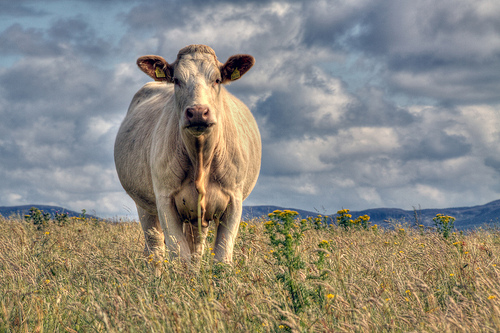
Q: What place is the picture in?
A: It is at the field.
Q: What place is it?
A: It is a field.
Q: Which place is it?
A: It is a field.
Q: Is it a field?
A: Yes, it is a field.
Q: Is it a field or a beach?
A: It is a field.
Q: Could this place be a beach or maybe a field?
A: It is a field.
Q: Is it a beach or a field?
A: It is a field.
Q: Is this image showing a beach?
A: No, the picture is showing a field.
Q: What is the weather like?
A: It is cloudy.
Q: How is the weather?
A: It is cloudy.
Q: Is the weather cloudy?
A: Yes, it is cloudy.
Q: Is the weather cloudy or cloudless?
A: It is cloudy.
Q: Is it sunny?
A: No, it is cloudy.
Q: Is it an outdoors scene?
A: Yes, it is outdoors.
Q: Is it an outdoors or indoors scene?
A: It is outdoors.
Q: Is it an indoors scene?
A: No, it is outdoors.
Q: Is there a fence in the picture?
A: No, there are no fences.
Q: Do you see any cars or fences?
A: No, there are no fences or cars.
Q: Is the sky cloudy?
A: Yes, the sky is cloudy.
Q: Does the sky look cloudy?
A: Yes, the sky is cloudy.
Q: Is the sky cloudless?
A: No, the sky is cloudy.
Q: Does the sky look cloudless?
A: No, the sky is cloudy.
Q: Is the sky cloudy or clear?
A: The sky is cloudy.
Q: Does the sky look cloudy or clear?
A: The sky is cloudy.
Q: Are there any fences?
A: No, there are no fences.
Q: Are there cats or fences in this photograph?
A: No, there are no fences or cats.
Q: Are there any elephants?
A: No, there are no elephants.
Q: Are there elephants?
A: No, there are no elephants.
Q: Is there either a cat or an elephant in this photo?
A: No, there are no elephants or cats.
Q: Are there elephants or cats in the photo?
A: No, there are no elephants or cats.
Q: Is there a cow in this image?
A: Yes, there is a cow.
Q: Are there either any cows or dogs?
A: Yes, there is a cow.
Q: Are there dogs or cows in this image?
A: Yes, there is a cow.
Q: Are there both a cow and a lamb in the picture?
A: No, there is a cow but no lambs.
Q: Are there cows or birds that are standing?
A: Yes, the cow is standing.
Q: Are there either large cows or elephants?
A: Yes, there is a large cow.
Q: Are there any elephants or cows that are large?
A: Yes, the cow is large.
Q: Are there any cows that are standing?
A: Yes, there is a cow that is standing.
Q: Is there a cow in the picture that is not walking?
A: Yes, there is a cow that is standing.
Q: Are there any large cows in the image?
A: Yes, there is a large cow.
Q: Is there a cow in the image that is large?
A: Yes, there is a cow that is large.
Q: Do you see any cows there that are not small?
A: Yes, there is a large cow.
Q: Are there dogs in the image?
A: No, there are no dogs.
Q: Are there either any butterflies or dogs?
A: No, there are no dogs or butterflies.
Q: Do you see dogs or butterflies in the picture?
A: No, there are no dogs or butterflies.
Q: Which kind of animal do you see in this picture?
A: The animal is a cow.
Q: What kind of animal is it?
A: The animal is a cow.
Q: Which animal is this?
A: This is a cow.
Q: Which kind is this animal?
A: This is a cow.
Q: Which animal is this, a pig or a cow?
A: This is a cow.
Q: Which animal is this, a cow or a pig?
A: This is a cow.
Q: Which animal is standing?
A: The animal is a cow.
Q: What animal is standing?
A: The animal is a cow.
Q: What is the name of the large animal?
A: The animal is a cow.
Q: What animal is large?
A: The animal is a cow.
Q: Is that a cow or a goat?
A: That is a cow.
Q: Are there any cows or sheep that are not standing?
A: No, there is a cow but it is standing.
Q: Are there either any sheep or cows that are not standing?
A: No, there is a cow but it is standing.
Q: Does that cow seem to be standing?
A: Yes, the cow is standing.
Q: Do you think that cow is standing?
A: Yes, the cow is standing.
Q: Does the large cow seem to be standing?
A: Yes, the cow is standing.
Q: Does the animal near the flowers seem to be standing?
A: Yes, the cow is standing.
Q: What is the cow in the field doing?
A: The cow is standing.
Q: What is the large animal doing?
A: The cow is standing.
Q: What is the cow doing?
A: The cow is standing.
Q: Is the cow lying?
A: No, the cow is standing.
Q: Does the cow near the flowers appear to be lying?
A: No, the cow is standing.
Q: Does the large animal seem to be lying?
A: No, the cow is standing.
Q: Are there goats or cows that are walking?
A: No, there is a cow but it is standing.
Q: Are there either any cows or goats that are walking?
A: No, there is a cow but it is standing.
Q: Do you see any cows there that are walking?
A: No, there is a cow but it is standing.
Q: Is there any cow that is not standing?
A: No, there is a cow but it is standing.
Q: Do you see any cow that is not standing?
A: No, there is a cow but it is standing.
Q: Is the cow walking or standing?
A: The cow is standing.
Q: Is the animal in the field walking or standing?
A: The cow is standing.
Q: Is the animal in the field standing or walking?
A: The cow is standing.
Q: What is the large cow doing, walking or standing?
A: The cow is standing.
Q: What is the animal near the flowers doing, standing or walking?
A: The cow is standing.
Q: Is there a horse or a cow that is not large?
A: No, there is a cow but it is large.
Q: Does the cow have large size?
A: Yes, the cow is large.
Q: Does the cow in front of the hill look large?
A: Yes, the cow is large.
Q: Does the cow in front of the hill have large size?
A: Yes, the cow is large.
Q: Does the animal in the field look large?
A: Yes, the cow is large.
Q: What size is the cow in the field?
A: The cow is large.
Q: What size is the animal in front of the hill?
A: The cow is large.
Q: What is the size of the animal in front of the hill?
A: The cow is large.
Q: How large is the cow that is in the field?
A: The cow is large.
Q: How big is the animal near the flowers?
A: The cow is large.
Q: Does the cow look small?
A: No, the cow is large.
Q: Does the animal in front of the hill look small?
A: No, the cow is large.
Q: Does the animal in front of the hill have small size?
A: No, the cow is large.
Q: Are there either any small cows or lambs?
A: No, there is a cow but it is large.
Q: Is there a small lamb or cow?
A: No, there is a cow but it is large.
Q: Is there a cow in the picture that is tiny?
A: No, there is a cow but it is large.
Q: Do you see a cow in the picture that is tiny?
A: No, there is a cow but it is large.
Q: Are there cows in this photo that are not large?
A: No, there is a cow but it is large.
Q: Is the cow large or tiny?
A: The cow is large.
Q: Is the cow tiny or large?
A: The cow is large.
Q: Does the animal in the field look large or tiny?
A: The cow is large.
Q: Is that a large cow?
A: Yes, that is a large cow.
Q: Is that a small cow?
A: No, that is a large cow.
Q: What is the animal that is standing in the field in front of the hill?
A: The animal is a cow.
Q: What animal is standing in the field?
A: The animal is a cow.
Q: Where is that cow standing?
A: The cow is standing in the field.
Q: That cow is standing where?
A: The cow is standing in the field.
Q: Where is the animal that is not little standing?
A: The cow is standing in the field.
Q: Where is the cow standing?
A: The cow is standing in the field.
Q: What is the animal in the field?
A: The animal is a cow.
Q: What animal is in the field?
A: The animal is a cow.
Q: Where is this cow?
A: The cow is in the field.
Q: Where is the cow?
A: The cow is in the field.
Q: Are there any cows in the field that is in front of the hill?
A: Yes, there is a cow in the field.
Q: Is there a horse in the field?
A: No, there is a cow in the field.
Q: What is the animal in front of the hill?
A: The animal is a cow.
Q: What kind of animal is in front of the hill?
A: The animal is a cow.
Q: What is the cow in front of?
A: The cow is in front of the hill.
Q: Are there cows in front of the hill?
A: Yes, there is a cow in front of the hill.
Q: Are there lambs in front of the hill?
A: No, there is a cow in front of the hill.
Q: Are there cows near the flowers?
A: Yes, there is a cow near the flowers.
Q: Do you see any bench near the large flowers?
A: No, there is a cow near the flowers.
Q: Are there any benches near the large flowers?
A: No, there is a cow near the flowers.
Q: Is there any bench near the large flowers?
A: No, there is a cow near the flowers.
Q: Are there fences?
A: No, there are no fences.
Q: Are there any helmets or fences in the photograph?
A: No, there are no fences or helmets.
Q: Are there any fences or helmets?
A: No, there are no fences or helmets.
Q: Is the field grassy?
A: Yes, the field is grassy.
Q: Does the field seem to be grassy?
A: Yes, the field is grassy.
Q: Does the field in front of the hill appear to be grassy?
A: Yes, the field is grassy.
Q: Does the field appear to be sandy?
A: No, the field is grassy.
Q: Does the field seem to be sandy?
A: No, the field is grassy.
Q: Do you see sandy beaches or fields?
A: No, there is a field but it is grassy.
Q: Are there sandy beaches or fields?
A: No, there is a field but it is grassy.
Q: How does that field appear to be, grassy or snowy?
A: The field is grassy.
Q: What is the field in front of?
A: The field is in front of the hill.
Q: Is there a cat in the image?
A: No, there are no cats.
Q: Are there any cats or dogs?
A: No, there are no cats or dogs.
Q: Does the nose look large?
A: Yes, the nose is large.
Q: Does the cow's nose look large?
A: Yes, the nose is large.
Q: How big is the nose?
A: The nose is large.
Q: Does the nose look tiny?
A: No, the nose is large.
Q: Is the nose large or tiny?
A: The nose is large.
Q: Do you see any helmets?
A: No, there are no helmets.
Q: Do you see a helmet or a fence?
A: No, there are no helmets or fences.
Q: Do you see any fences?
A: No, there are no fences.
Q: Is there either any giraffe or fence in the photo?
A: No, there are no fences or giraffes.